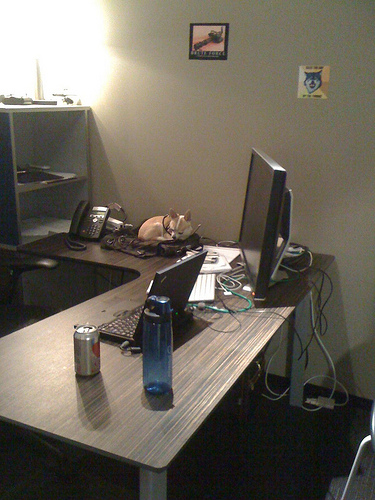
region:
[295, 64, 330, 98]
poster of grey dog hanging on wall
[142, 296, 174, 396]
blue plastic water bottle on wood desk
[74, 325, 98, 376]
silver and read pepsi van on wood desk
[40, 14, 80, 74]
sunlight shining on wall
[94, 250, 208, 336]
black laptop open on desk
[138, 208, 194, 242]
yellow and white chiwawa lying on desk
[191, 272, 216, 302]
white keyboard on wooden desk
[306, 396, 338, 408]
tan keyboard connector on floor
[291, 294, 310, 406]
grey leg holding up desk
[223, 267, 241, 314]
messy computer cord laying on desk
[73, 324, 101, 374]
soda can sitting on computer desk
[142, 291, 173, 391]
tall blue water bottle sitting on desk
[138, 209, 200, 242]
dog figurine laying on computer desk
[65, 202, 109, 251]
black phone sitting on computer desk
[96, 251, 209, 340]
small black laptop on desk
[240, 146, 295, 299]
black computer monitor sitting on desk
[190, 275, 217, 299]
white computer keyboard on desk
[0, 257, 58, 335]
black computer chair near desk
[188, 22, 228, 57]
paper picture hanging on wall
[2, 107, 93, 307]
wooden cabinet sitting against the wall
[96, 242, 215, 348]
A laptop computer in the foreground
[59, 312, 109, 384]
A can of coke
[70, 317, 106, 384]
Can is silver in color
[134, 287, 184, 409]
A blue bottle in the foreground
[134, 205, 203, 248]
A small dog in the background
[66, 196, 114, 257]
A black home phone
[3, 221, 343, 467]
Table is made of wood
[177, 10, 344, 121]
Posters on the wall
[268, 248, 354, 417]
Computer and electronic plugs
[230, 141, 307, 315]
A desktop computer screen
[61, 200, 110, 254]
A phone on a desk.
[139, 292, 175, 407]
A empty blue bottle.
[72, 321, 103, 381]
A can of soda.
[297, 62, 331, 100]
A picture on the wall.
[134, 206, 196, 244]
A brown dog on the desk.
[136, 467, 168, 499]
One of the desk legs.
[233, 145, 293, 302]
A computer monitor on the desk.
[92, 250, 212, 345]
A open black laptop.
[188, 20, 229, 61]
A picture on the wall with black trim.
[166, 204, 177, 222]
A ear of a dog.